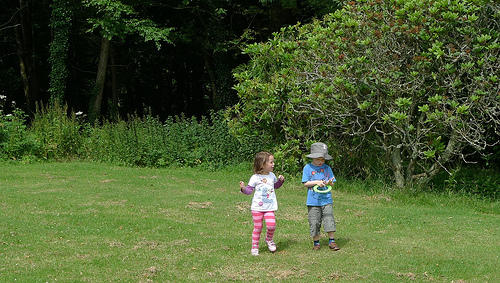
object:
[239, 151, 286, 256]
girl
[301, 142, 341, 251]
boy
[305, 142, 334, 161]
hat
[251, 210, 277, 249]
tights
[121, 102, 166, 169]
plants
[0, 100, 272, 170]
row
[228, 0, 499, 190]
tree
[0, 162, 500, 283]
grass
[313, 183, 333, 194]
toy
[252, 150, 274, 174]
hair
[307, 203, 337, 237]
shorts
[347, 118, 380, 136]
branches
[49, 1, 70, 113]
tree trunk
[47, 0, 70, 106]
vines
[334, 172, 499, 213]
tall grass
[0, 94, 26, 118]
queen annes lace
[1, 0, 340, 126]
forest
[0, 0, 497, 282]
backyard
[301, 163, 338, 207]
t-shirt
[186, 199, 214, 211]
pile of grass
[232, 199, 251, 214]
pile of grass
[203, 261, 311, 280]
pile of grass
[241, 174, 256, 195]
arms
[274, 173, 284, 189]
arms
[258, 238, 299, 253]
shadow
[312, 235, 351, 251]
shadow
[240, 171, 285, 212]
shirt